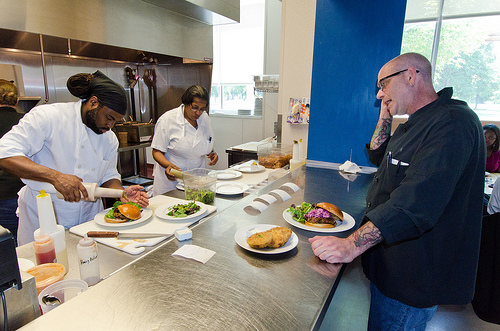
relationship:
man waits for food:
[342, 29, 499, 329] [276, 185, 363, 233]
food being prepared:
[276, 185, 363, 233] [107, 188, 160, 209]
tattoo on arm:
[381, 120, 391, 141] [355, 233, 382, 251]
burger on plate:
[313, 204, 343, 229] [290, 219, 308, 230]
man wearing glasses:
[342, 29, 499, 329] [371, 70, 392, 87]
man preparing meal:
[342, 29, 499, 329] [110, 196, 149, 221]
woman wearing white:
[151, 77, 224, 181] [168, 126, 183, 155]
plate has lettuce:
[290, 219, 308, 230] [176, 203, 197, 231]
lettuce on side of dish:
[176, 203, 197, 231] [160, 209, 165, 221]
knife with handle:
[88, 228, 169, 239] [84, 230, 121, 240]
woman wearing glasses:
[151, 77, 224, 181] [371, 70, 392, 87]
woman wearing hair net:
[151, 77, 224, 181] [181, 81, 209, 96]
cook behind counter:
[3, 79, 24, 120] [305, 169, 321, 186]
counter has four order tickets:
[305, 169, 321, 186] [229, 178, 311, 214]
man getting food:
[342, 29, 499, 329] [276, 185, 363, 233]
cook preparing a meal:
[3, 79, 24, 120] [110, 196, 149, 221]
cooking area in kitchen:
[110, 177, 347, 285] [12, 12, 495, 330]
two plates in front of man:
[228, 194, 363, 257] [342, 29, 499, 329]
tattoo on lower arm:
[381, 120, 391, 141] [321, 226, 376, 260]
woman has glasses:
[151, 77, 224, 181] [371, 70, 392, 87]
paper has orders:
[165, 242, 219, 270] [247, 188, 275, 215]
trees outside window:
[445, 38, 493, 85] [401, 1, 499, 120]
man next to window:
[308, 52, 487, 331] [401, 1, 499, 120]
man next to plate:
[308, 52, 487, 331] [282, 210, 356, 232]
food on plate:
[288, 202, 343, 229] [282, 210, 356, 232]